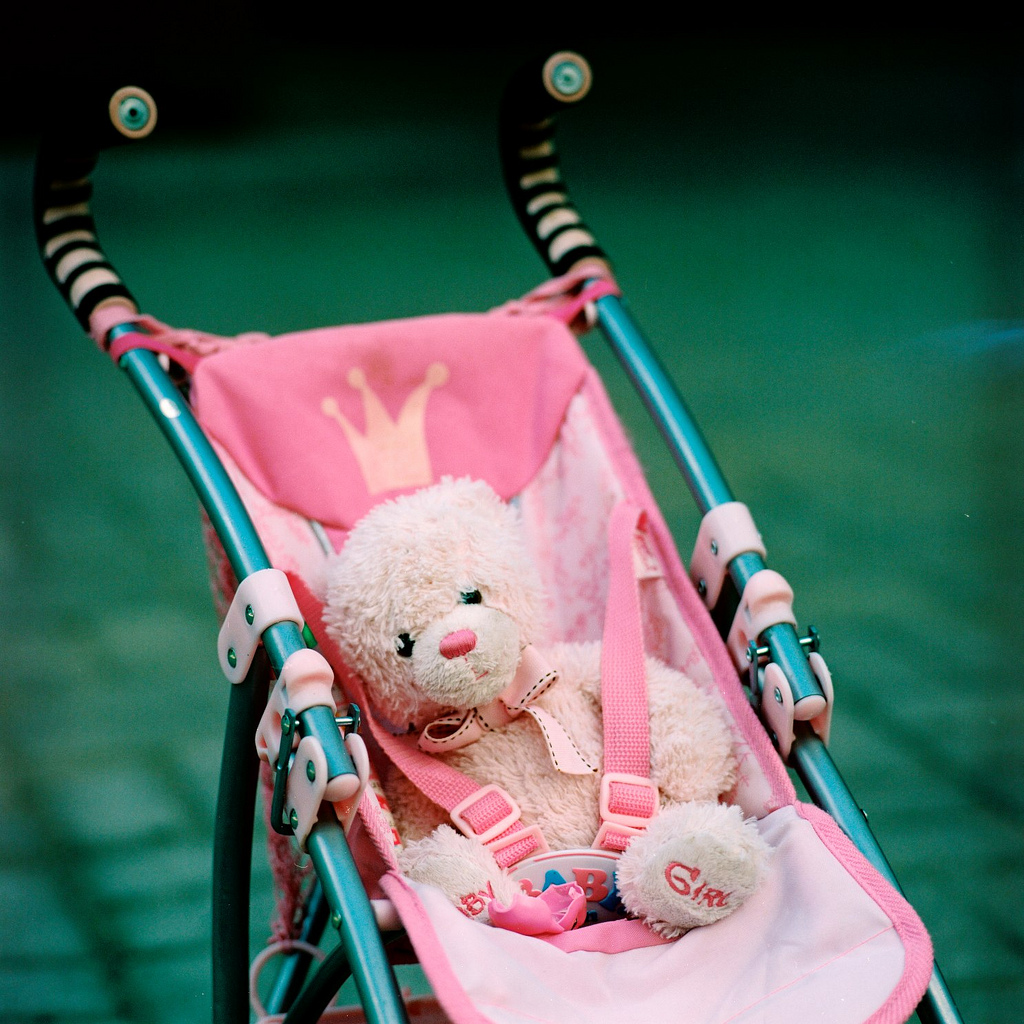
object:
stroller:
[28, 54, 964, 1021]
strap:
[285, 569, 548, 875]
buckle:
[451, 781, 550, 874]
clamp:
[217, 569, 305, 686]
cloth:
[87, 255, 931, 1022]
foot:
[395, 824, 515, 922]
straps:
[591, 499, 660, 852]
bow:
[417, 643, 597, 775]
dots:
[532, 685, 537, 689]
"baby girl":
[321, 473, 762, 942]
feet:
[614, 800, 772, 939]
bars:
[107, 328, 357, 805]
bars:
[594, 293, 827, 722]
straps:
[269, 503, 657, 878]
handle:
[498, 50, 611, 278]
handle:
[30, 85, 158, 334]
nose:
[440, 630, 476, 660]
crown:
[320, 362, 449, 496]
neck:
[421, 644, 542, 737]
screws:
[283, 732, 370, 854]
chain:
[258, 753, 312, 956]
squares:
[13, 736, 209, 863]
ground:
[0, 0, 1024, 1024]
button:
[460, 585, 482, 603]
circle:
[543, 50, 592, 103]